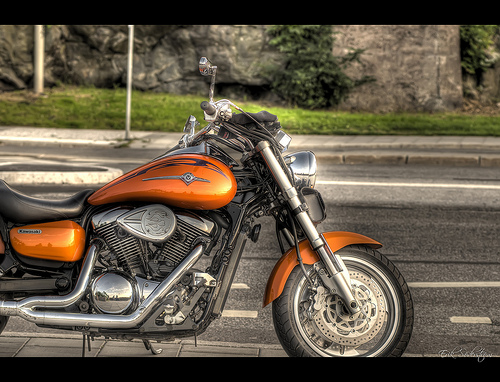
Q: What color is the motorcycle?
A: Orange.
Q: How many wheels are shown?
A: One.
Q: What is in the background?
A: A stone cliff.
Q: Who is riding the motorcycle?
A: No one.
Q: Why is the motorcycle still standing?
A: The kickstand.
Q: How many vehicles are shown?
A: One.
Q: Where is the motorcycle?
A: Parked near a road.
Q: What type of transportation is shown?
A: Motorcycle.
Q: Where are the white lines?
A: Road.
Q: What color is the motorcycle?
A: Orange.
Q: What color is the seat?
A: Black.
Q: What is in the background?
A: Rock wall.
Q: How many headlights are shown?
A: One.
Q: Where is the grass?
A: Left side of the road.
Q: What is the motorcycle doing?
A: Parked.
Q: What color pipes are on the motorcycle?
A: Silver.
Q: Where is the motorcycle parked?
A: Sidewalk.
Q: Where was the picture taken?
A: On a street.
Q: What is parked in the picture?
A: A motorcycle.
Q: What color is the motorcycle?
A: Orange.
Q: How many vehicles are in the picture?
A: 1.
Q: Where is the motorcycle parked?
A: On a sidewalk.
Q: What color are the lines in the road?
A: White.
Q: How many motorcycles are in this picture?
A: One.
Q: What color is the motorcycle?
A: Orange and black.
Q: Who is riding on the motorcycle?
A: No one.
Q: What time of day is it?
A: Daytime.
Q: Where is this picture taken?
A: The street.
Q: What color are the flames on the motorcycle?
A: Black.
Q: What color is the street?
A: Black.